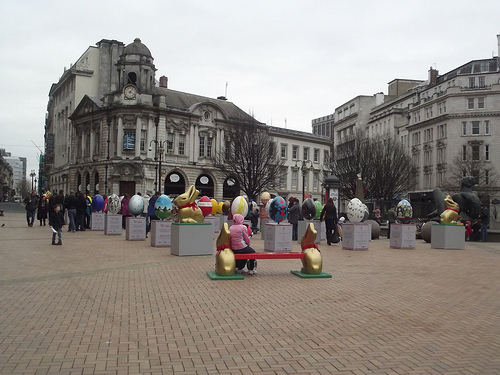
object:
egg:
[153, 193, 176, 222]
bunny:
[170, 183, 207, 225]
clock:
[122, 83, 138, 100]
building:
[65, 33, 338, 223]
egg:
[127, 193, 146, 218]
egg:
[299, 196, 318, 222]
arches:
[162, 166, 191, 200]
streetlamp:
[166, 138, 176, 156]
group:
[285, 196, 305, 241]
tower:
[112, 33, 159, 108]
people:
[46, 202, 69, 247]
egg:
[91, 193, 107, 213]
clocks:
[169, 173, 181, 183]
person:
[320, 197, 345, 245]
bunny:
[298, 220, 328, 276]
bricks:
[114, 280, 130, 293]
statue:
[389, 198, 418, 252]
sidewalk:
[0, 253, 499, 375]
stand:
[388, 223, 419, 251]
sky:
[0, 0, 499, 131]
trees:
[210, 106, 288, 204]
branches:
[210, 156, 238, 172]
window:
[119, 125, 138, 152]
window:
[176, 130, 190, 156]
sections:
[164, 117, 333, 168]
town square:
[0, 188, 500, 375]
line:
[0, 252, 176, 288]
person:
[49, 200, 66, 245]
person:
[73, 190, 89, 231]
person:
[21, 189, 41, 229]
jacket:
[228, 212, 251, 250]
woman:
[227, 212, 261, 276]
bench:
[212, 246, 325, 280]